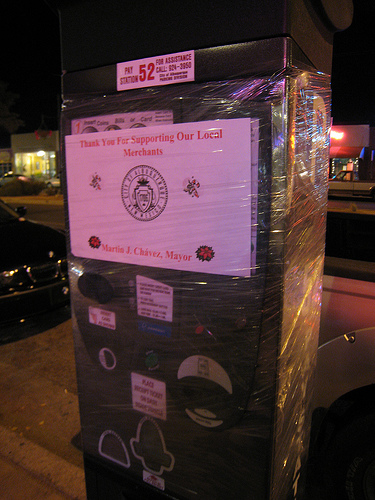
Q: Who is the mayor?
A: Martin J. Chavez.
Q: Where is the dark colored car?
A: On the left?.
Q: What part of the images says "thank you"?
A: The white sign.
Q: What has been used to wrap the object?
A: Plastic wrap.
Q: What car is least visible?
A: The white car.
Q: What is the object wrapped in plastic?
A: A parking meter.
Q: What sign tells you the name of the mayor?
A: The white sign on the meter.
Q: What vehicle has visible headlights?
A: The black vehicle.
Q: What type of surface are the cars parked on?
A: Concrete.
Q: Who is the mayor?
A: Martin J. Chavez.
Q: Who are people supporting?
A: The local merchants.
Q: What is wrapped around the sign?
A: Plastic wrap.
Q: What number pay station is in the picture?
A: 52.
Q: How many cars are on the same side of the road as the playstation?
A: Two.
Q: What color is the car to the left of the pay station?
A: Black.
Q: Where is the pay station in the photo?
A: Bottom center.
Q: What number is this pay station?
A: 52.